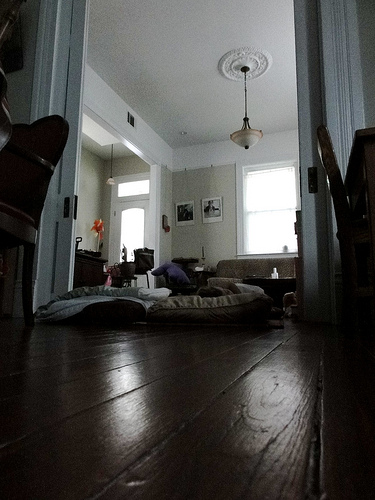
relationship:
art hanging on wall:
[199, 194, 223, 223] [174, 149, 235, 258]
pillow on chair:
[153, 259, 189, 282] [153, 255, 199, 291]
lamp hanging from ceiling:
[229, 64, 265, 152] [86, 1, 298, 148]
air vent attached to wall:
[123, 107, 141, 130] [187, 253, 242, 261]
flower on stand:
[87, 216, 104, 252] [96, 231, 100, 251]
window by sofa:
[240, 159, 302, 255] [209, 257, 297, 291]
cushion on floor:
[152, 288, 267, 318] [22, 311, 330, 497]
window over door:
[113, 177, 149, 198] [115, 199, 151, 262]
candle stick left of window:
[201, 256, 206, 269] [239, 165, 303, 251]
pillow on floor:
[144, 290, 267, 320] [0, 317, 373, 498]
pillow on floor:
[33, 285, 172, 325] [0, 317, 373, 498]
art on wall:
[199, 194, 223, 223] [157, 156, 236, 270]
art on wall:
[174, 199, 195, 226] [157, 156, 236, 270]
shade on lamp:
[231, 126, 264, 149] [229, 64, 265, 152]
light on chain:
[104, 175, 116, 186] [108, 145, 114, 179]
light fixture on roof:
[215, 46, 274, 153] [93, 7, 305, 147]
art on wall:
[199, 194, 223, 223] [170, 128, 303, 271]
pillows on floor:
[35, 283, 171, 310] [16, 325, 373, 492]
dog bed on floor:
[38, 283, 268, 330] [16, 325, 373, 492]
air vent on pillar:
[123, 107, 141, 130] [85, 72, 189, 202]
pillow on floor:
[144, 290, 267, 320] [22, 311, 330, 497]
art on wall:
[174, 199, 195, 226] [170, 128, 303, 271]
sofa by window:
[209, 257, 297, 291] [240, 159, 302, 255]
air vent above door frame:
[123, 107, 141, 130] [72, 106, 155, 288]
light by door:
[104, 175, 116, 186] [112, 201, 145, 287]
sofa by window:
[209, 257, 297, 291] [235, 153, 300, 259]